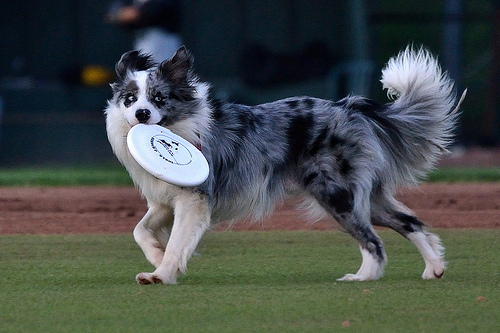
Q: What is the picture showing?
A: It is showing a field.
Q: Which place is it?
A: It is a field.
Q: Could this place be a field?
A: Yes, it is a field.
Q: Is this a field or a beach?
A: It is a field.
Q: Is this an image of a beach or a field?
A: It is showing a field.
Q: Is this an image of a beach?
A: No, the picture is showing a field.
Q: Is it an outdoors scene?
A: Yes, it is outdoors.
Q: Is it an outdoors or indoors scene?
A: It is outdoors.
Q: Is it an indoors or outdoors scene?
A: It is outdoors.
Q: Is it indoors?
A: No, it is outdoors.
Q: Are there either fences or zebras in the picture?
A: No, there are no fences or zebras.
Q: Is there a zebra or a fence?
A: No, there are no fences or zebras.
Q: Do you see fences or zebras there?
A: No, there are no fences or zebras.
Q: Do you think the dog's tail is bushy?
A: Yes, the tail is bushy.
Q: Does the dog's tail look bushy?
A: Yes, the tail is bushy.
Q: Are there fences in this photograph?
A: No, there are no fences.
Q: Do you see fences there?
A: No, there are no fences.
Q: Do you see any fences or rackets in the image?
A: No, there are no fences or rackets.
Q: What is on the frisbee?
A: The logo is on the frisbee.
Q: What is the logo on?
A: The logo is on the frisbee.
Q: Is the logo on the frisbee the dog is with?
A: Yes, the logo is on the frisbee.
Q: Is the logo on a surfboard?
A: No, the logo is on the frisbee.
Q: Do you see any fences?
A: No, there are no fences.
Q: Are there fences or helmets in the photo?
A: No, there are no fences or helmets.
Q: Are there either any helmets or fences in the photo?
A: No, there are no fences or helmets.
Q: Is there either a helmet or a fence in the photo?
A: No, there are no fences or helmets.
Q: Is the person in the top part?
A: Yes, the person is in the top of the image.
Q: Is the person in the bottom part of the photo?
A: No, the person is in the top of the image.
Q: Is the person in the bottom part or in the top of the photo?
A: The person is in the top of the image.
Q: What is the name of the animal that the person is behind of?
A: The animal is a dog.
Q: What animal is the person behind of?
A: The person is behind the dog.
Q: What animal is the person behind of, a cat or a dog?
A: The person is behind a dog.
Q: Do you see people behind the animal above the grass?
A: Yes, there is a person behind the dog.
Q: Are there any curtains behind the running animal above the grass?
A: No, there is a person behind the dog.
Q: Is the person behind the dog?
A: Yes, the person is behind the dog.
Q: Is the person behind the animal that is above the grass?
A: Yes, the person is behind the dog.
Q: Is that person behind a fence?
A: No, the person is behind the dog.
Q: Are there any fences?
A: No, there are no fences.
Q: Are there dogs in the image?
A: Yes, there is a dog.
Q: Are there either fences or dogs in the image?
A: Yes, there is a dog.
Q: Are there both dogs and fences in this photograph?
A: No, there is a dog but no fences.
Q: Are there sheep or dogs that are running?
A: Yes, the dog is running.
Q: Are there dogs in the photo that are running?
A: Yes, there is a dog that is running.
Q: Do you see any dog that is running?
A: Yes, there is a dog that is running.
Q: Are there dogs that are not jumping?
A: Yes, there is a dog that is running.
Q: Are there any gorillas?
A: No, there are no gorillas.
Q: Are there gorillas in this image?
A: No, there are no gorillas.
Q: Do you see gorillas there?
A: No, there are no gorillas.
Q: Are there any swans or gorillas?
A: No, there are no gorillas or swans.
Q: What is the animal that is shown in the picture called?
A: The animal is a dog.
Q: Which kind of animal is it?
A: The animal is a dog.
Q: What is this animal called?
A: This is a dog.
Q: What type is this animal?
A: This is a dog.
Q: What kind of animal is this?
A: This is a dog.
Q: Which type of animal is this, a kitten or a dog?
A: This is a dog.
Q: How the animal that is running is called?
A: The animal is a dog.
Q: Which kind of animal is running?
A: The animal is a dog.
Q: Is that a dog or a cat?
A: That is a dog.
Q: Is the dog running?
A: Yes, the dog is running.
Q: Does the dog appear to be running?
A: Yes, the dog is running.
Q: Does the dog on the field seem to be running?
A: Yes, the dog is running.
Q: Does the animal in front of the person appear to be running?
A: Yes, the dog is running.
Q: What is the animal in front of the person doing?
A: The dog is running.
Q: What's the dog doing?
A: The dog is running.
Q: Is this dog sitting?
A: No, the dog is running.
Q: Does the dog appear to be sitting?
A: No, the dog is running.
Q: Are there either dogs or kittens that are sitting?
A: No, there is a dog but it is running.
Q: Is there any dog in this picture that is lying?
A: No, there is a dog but it is running.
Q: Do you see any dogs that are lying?
A: No, there is a dog but it is running.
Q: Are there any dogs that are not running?
A: No, there is a dog but it is running.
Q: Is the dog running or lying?
A: The dog is running.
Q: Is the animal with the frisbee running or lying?
A: The dog is running.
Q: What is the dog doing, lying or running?
A: The dog is running.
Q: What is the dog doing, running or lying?
A: The dog is running.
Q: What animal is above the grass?
A: The animal is a dog.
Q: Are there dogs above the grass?
A: Yes, there is a dog above the grass.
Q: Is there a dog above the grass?
A: Yes, there is a dog above the grass.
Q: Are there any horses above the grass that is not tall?
A: No, there is a dog above the grass.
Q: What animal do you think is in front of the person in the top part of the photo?
A: The dog is in front of the person.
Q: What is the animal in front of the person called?
A: The animal is a dog.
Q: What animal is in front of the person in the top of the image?
A: The animal is a dog.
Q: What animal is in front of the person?
A: The animal is a dog.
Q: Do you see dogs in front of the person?
A: Yes, there is a dog in front of the person.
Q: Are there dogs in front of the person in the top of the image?
A: Yes, there is a dog in front of the person.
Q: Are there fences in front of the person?
A: No, there is a dog in front of the person.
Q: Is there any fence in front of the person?
A: No, there is a dog in front of the person.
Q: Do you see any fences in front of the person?
A: No, there is a dog in front of the person.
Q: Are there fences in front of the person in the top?
A: No, there is a dog in front of the person.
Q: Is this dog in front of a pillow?
A: No, the dog is in front of the person.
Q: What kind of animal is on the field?
A: The animal is a dog.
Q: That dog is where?
A: The dog is on the field.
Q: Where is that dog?
A: The dog is on the field.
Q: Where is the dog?
A: The dog is on the field.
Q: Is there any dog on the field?
A: Yes, there is a dog on the field.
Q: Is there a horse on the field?
A: No, there is a dog on the field.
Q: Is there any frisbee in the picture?
A: Yes, there is a frisbee.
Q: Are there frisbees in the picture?
A: Yes, there is a frisbee.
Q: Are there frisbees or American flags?
A: Yes, there is a frisbee.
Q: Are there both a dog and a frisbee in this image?
A: Yes, there are both a frisbee and a dog.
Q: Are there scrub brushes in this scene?
A: No, there are no scrub brushes.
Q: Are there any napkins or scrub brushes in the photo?
A: No, there are no scrub brushes or napkins.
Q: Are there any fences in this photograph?
A: No, there are no fences.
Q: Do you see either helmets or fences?
A: No, there are no fences or helmets.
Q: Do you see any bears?
A: No, there are no bears.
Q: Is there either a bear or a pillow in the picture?
A: No, there are no bears or pillows.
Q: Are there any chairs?
A: Yes, there is a chair.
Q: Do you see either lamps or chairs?
A: Yes, there is a chair.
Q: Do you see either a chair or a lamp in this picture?
A: Yes, there is a chair.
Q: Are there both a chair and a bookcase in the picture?
A: No, there is a chair but no bookcases.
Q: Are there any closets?
A: No, there are no closets.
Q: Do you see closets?
A: No, there are no closets.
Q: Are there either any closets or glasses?
A: No, there are no closets or glasses.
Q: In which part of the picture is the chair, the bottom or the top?
A: The chair is in the top of the image.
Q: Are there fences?
A: No, there are no fences.